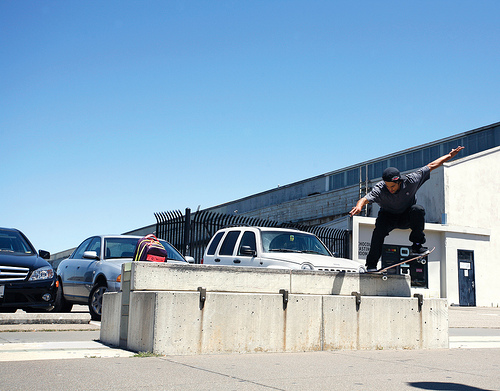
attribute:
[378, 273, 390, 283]
wheel — white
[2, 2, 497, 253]
sky — clear, blue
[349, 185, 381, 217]
arm — raised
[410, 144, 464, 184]
arm — raised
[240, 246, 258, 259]
mirror — black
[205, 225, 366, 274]
vehicle — white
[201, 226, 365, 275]
jeep — white, parked, Liberty model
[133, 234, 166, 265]
backpack — red, tan, brown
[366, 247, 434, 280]
skateboard — grind, grind position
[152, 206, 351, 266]
fence — tall, black, metal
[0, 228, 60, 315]
car — black, parked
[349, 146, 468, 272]
man — performing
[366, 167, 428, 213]
shirt — grey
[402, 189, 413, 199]
symbol — white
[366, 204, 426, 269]
pants — black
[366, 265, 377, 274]
sneaker — black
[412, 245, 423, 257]
sneaker — black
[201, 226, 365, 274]
van — white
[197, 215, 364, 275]
car — white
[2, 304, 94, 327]
block — grey, concrete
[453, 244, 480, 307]
door — black, metal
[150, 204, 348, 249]
fence — black, metal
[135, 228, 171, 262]
backpack — black, neon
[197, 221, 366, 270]
jeep — white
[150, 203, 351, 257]
fence — black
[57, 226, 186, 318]
car — black, silver